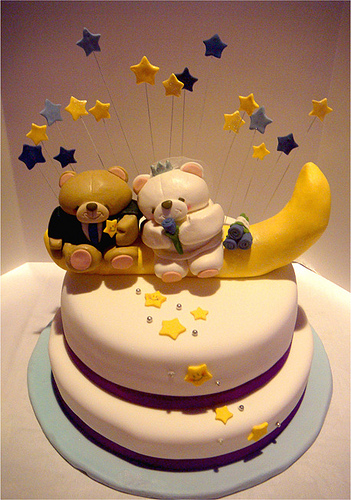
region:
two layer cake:
[22, 263, 335, 499]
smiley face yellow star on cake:
[180, 360, 214, 389]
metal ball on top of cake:
[141, 313, 155, 324]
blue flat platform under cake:
[23, 318, 335, 498]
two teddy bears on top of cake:
[43, 161, 233, 282]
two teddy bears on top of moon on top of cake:
[42, 160, 334, 282]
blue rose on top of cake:
[156, 216, 190, 257]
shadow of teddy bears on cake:
[59, 268, 243, 303]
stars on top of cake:
[8, 20, 338, 233]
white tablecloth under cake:
[1, 255, 347, 493]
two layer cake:
[10, 25, 344, 498]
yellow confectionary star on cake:
[158, 312, 188, 343]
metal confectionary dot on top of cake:
[140, 311, 155, 325]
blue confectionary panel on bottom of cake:
[24, 310, 333, 499]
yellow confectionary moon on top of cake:
[41, 153, 333, 277]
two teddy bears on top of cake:
[46, 161, 224, 285]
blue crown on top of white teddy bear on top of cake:
[143, 158, 180, 178]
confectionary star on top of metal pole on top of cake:
[15, 22, 333, 208]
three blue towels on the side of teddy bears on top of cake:
[222, 209, 255, 252]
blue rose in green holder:
[156, 212, 188, 256]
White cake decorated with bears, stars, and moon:
[22, 24, 350, 499]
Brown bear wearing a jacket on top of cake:
[46, 163, 140, 272]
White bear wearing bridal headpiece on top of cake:
[133, 154, 225, 280]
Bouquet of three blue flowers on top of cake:
[224, 214, 252, 250]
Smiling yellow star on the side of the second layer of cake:
[184, 363, 213, 387]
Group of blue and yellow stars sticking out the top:
[9, 24, 331, 167]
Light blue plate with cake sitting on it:
[27, 322, 333, 496]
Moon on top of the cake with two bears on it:
[43, 162, 334, 276]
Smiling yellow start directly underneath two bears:
[143, 289, 167, 308]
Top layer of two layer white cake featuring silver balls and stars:
[60, 274, 297, 396]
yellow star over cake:
[62, 94, 89, 119]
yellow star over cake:
[22, 116, 52, 146]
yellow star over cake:
[88, 99, 108, 132]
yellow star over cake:
[136, 60, 159, 80]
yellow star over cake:
[159, 77, 177, 95]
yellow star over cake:
[218, 109, 243, 131]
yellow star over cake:
[241, 90, 259, 117]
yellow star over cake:
[254, 140, 267, 160]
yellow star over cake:
[314, 103, 326, 117]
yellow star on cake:
[158, 317, 184, 337]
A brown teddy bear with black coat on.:
[48, 166, 138, 273]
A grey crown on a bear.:
[149, 159, 173, 176]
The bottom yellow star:
[248, 421, 269, 441]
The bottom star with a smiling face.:
[185, 364, 211, 387]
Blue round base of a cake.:
[26, 318, 334, 499]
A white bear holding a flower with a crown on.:
[131, 160, 224, 281]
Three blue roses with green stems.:
[224, 213, 254, 249]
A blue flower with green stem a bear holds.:
[161, 217, 183, 254]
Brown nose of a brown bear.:
[85, 201, 97, 211]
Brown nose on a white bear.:
[161, 199, 173, 207]